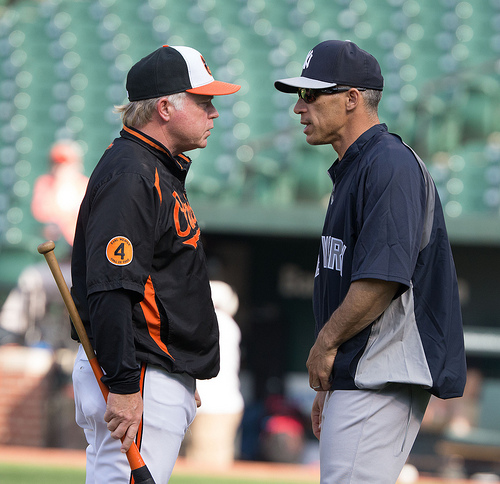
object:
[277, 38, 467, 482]
baseball player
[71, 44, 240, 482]
baseball coach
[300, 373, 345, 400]
ring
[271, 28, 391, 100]
cap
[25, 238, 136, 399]
bat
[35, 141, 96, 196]
spectacle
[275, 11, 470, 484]
men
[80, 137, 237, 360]
jacket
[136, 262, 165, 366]
stripe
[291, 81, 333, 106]
glass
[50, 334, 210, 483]
pant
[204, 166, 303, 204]
seat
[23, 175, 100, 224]
shirt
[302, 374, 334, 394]
finger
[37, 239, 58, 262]
base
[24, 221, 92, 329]
handle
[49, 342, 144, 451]
handl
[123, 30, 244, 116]
hat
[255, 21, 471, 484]
people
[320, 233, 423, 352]
arm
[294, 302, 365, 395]
hand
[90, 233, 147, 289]
number